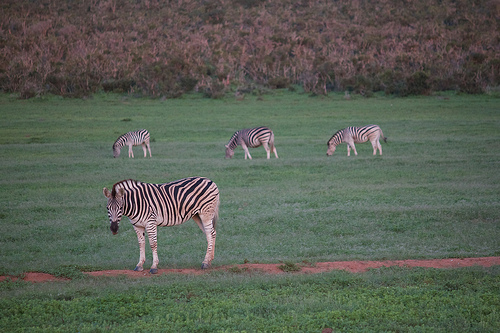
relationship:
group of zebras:
[96, 90, 390, 285] [97, 116, 385, 303]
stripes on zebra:
[140, 183, 198, 216] [84, 166, 245, 328]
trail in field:
[32, 256, 497, 275] [54, 243, 302, 333]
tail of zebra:
[379, 124, 400, 146] [313, 116, 402, 164]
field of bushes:
[419, 103, 462, 223] [44, 10, 219, 98]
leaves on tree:
[404, 57, 421, 70] [352, 15, 441, 85]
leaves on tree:
[406, 70, 435, 97] [372, 34, 413, 76]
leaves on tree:
[406, 70, 435, 97] [200, 20, 301, 92]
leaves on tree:
[406, 70, 435, 97] [224, 31, 296, 76]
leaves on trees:
[406, 70, 435, 97] [297, 23, 372, 86]